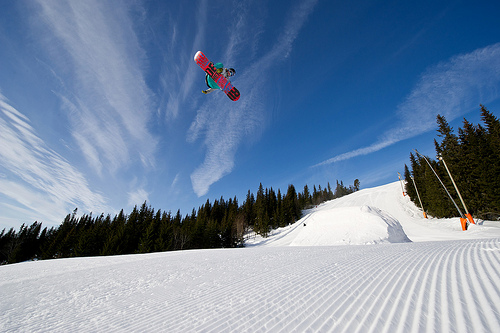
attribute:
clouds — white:
[10, 103, 222, 197]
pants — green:
[205, 59, 227, 88]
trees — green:
[0, 210, 241, 247]